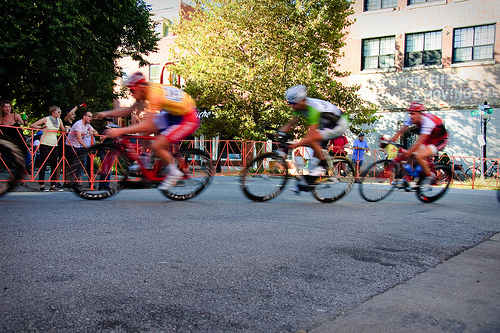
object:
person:
[89, 71, 202, 193]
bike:
[59, 101, 217, 204]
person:
[267, 82, 352, 196]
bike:
[234, 123, 358, 204]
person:
[376, 98, 451, 190]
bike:
[353, 133, 463, 206]